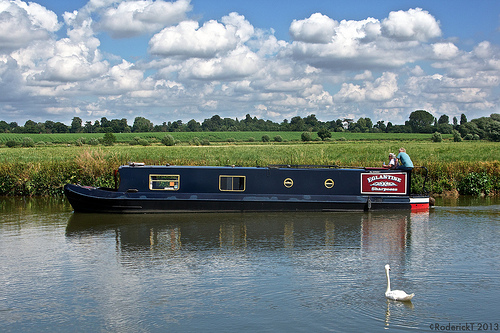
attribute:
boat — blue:
[62, 137, 440, 217]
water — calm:
[140, 222, 260, 317]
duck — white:
[375, 257, 422, 309]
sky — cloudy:
[1, 2, 497, 140]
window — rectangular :
[219, 172, 250, 191]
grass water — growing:
[5, 151, 88, 194]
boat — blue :
[60, 158, 427, 215]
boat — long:
[66, 168, 411, 210]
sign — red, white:
[358, 170, 410, 192]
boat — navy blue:
[58, 143, 466, 218]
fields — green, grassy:
[8, 114, 464, 186]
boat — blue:
[62, 162, 409, 213]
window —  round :
[323, 177, 334, 188]